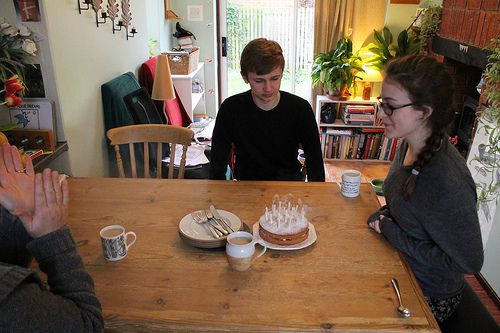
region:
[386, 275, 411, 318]
A sliver spoon at the edge of the table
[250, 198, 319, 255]
A cake with candles on top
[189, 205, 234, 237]
Assorted silverware on a stack of plates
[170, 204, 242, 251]
A stack of plates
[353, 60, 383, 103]
A lit desk lamp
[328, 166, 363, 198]
A white and black coffee cup on the corner of the table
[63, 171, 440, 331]
A wooden dining table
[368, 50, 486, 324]
A lady sitting at the table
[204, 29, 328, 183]
A young man sitting at the table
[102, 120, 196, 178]
The back of an empty wooden chair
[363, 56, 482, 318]
girl in a gray shirt with a braid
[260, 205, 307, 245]
birthday cake with candles blown out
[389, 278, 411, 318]
a silver spoon on the corner of the table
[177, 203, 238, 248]
a stack of plates with forks and knives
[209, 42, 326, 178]
a teenage boy in a black shirt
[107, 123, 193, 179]
an empty chair at the table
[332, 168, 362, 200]
a mug of coffee on the corner of the table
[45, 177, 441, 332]
a brown dining room table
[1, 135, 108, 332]
a person clapping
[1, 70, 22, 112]
red tulips on the left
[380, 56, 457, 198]
Girl's hair in french braid.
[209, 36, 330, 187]
Boy wearing black sweater.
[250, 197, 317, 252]
Birthday cake on white plate.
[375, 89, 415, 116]
Black glasses on girl's face.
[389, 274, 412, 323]
Silver spoon laying on table.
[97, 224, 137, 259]
Coffee cup full of coffee.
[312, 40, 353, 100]
Green plant on book shelf.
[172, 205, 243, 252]
Silverware on top of plates.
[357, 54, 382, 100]
Lamp on top of book shelf.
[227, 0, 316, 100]
Sun shining through sliding door.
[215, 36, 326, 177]
A man in a black top sitting in a chair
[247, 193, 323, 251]
A birthday cake with candles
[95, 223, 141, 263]
A mug of coffee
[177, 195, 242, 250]
A stack of plates with silverware on top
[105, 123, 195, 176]
The top of a wooden chair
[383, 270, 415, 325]
A single metal spoon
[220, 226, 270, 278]
A pitcher of cream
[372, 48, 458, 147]
A smiling girl with glasses seen in profile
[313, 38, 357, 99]
A healthy potted plant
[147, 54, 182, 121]
A modern style lamp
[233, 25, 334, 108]
the head of a man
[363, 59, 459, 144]
the head of a woman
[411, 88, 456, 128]
the ear of a woman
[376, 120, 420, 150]
the chin of a woman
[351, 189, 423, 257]
the hand of a woman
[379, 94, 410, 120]
the eye of a woman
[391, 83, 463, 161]
the neck of a woman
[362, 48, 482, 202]
the hair of a woman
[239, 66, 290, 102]
the eyes of a man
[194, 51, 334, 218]
a man wearing a shirt